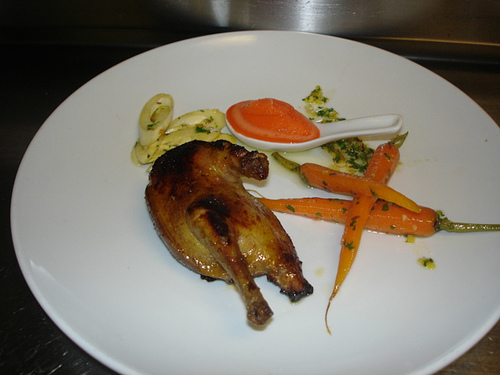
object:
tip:
[323, 252, 352, 335]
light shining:
[271, 0, 360, 33]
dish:
[10, 30, 498, 375]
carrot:
[254, 195, 499, 238]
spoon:
[225, 97, 405, 150]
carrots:
[270, 150, 422, 214]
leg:
[184, 207, 276, 325]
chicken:
[144, 138, 315, 325]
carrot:
[322, 129, 410, 334]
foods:
[129, 84, 500, 335]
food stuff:
[227, 97, 321, 144]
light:
[211, 0, 323, 35]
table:
[0, 0, 500, 375]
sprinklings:
[256, 131, 500, 336]